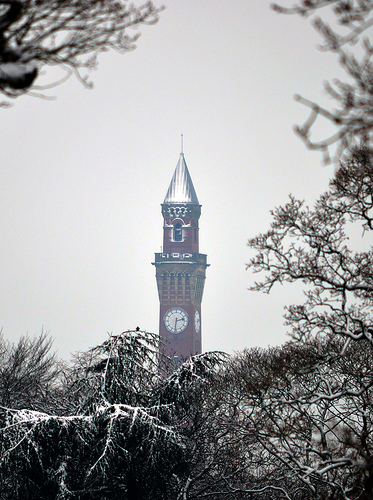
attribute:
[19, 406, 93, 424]
snow — white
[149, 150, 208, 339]
clock tower — clock 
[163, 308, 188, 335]
clock — white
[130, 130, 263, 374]
tower — clock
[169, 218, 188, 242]
window — small arched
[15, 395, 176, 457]
snow — white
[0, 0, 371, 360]
sky — cloudy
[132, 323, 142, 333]
bird — small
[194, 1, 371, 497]
tree — branchy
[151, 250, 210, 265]
balcony — black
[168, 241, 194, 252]
brick — red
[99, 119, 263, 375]
tower — tall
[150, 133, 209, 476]
tower — tall, skinny, red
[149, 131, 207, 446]
building — tall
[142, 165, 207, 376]
brick tower — large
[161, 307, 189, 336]
clock — white, round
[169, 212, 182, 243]
window — large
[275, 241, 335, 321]
branches —  tree 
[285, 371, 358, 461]
leaves — no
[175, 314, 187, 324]
hand — hour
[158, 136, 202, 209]
roof — covered